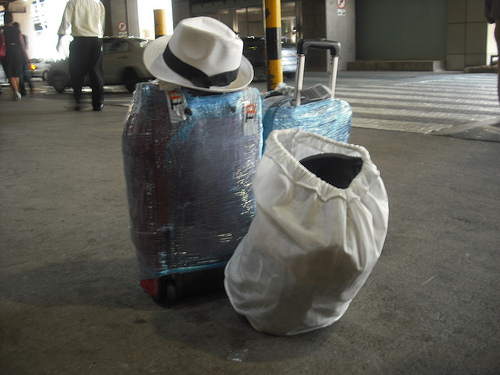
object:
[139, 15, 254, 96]
hat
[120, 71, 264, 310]
suitcase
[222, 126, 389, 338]
bag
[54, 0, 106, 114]
man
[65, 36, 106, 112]
pants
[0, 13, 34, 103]
woman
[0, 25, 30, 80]
dress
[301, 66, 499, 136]
crosswalk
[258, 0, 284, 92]
pillar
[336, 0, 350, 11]
sign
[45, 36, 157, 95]
car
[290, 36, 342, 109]
handle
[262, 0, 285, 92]
pole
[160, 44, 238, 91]
band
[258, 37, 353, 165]
suitcase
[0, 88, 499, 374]
walkway